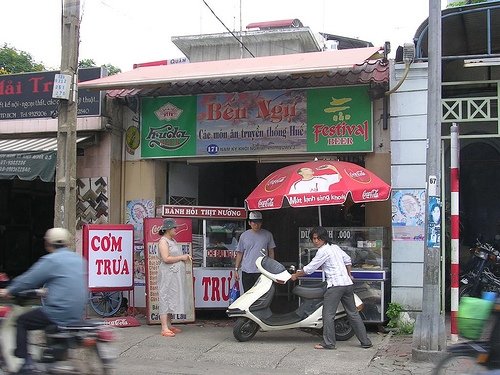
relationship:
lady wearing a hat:
[153, 217, 193, 335] [154, 217, 179, 231]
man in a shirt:
[289, 226, 373, 349] [299, 241, 352, 283]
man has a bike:
[287, 229, 373, 349] [224, 249, 365, 343]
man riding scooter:
[1, 224, 98, 369] [0, 289, 119, 374]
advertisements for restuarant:
[141, 80, 363, 156] [0, 0, 435, 337]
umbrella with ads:
[237, 154, 394, 226] [289, 158, 341, 200]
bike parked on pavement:
[210, 257, 355, 350] [145, 330, 242, 369]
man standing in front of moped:
[289, 226, 373, 349] [227, 245, 370, 350]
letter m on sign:
[101, 228, 134, 260] [63, 202, 157, 305]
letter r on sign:
[103, 257, 110, 277] [80, 223, 137, 294]